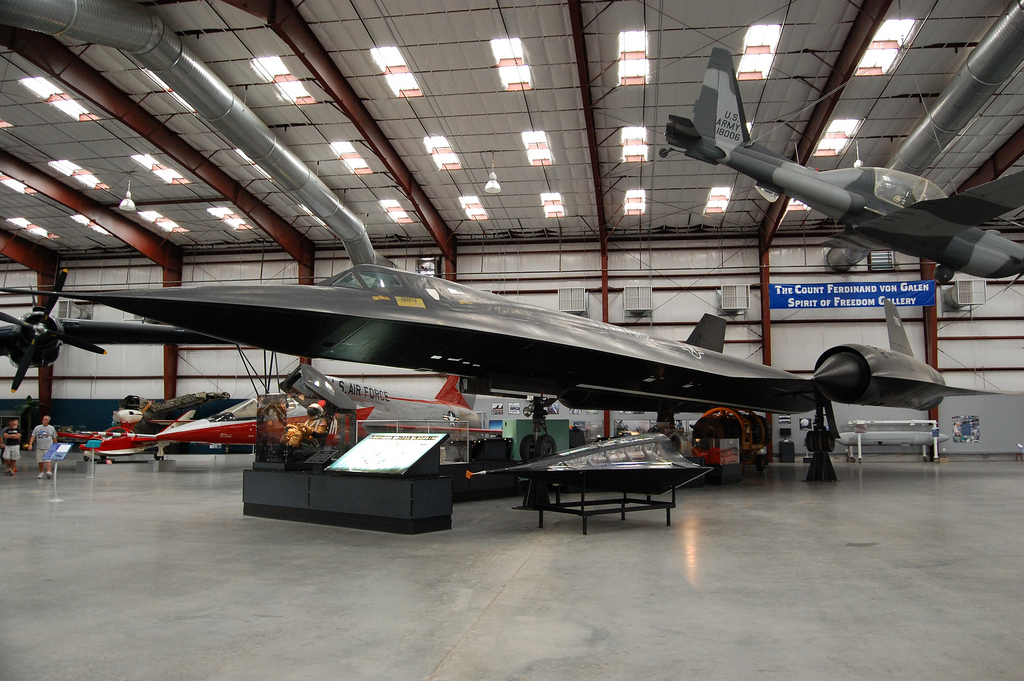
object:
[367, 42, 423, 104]
light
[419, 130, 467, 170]
light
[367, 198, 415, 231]
light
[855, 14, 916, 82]
light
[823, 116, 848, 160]
light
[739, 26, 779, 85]
light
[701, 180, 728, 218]
light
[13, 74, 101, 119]
light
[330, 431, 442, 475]
display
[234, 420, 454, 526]
counter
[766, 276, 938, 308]
sign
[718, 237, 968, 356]
wall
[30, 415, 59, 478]
man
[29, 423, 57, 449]
tee shirt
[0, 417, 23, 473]
man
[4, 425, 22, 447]
shirt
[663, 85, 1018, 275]
plane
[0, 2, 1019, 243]
ceiling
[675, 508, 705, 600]
glare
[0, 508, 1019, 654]
floor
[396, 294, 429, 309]
sticker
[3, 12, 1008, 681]
hangar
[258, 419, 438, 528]
plaque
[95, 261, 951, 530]
aircraft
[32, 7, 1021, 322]
building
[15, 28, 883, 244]
light